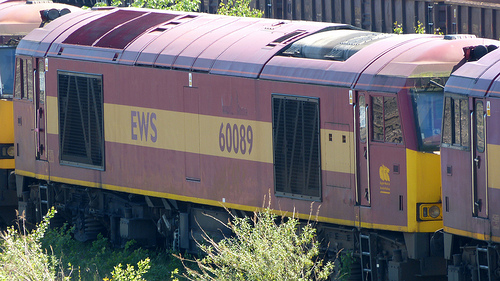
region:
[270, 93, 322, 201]
A metal ventilation grate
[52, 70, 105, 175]
A metal ventilation grate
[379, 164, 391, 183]
A yellow company logo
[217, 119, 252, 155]
An identification number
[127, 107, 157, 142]
The letters EWS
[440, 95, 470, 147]
A train windscreen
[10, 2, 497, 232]
A purple and yellow train car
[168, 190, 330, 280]
A green bush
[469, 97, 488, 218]
The door of a train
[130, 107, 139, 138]
The letter "E" in purple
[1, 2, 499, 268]
red and yellow abandoned train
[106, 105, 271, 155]
black letters and numbers on yellow stripe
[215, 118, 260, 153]
number 60089 on red train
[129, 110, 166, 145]
EWS on red train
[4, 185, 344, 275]
green bushes in foreground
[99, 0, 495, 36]
wooden fence in background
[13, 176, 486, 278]
black metal train wheels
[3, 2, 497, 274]
outdoor sunny daytime railroad scene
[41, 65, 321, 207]
black open doors on side of train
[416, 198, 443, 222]
round headlight in front of train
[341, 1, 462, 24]
brown train on track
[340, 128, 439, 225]
train has three colors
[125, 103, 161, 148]
ews is on the train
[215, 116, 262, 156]
60089 is on the train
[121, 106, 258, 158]
letters and numbers on tan area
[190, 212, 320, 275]
bush is green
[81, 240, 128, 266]
grass is green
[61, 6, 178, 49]
opening ontop of train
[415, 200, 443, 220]
light is round on train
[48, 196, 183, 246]
bottom of train is black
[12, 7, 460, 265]
red and yellow train engine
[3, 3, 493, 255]
three train engines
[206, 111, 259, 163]
numbers painted on engine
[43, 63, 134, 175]
exhaust vent on train engine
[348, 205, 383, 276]
steps to train entrance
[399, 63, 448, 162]
windshield on train engine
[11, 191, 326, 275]
overgrown weeds beside tracks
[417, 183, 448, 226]
headlight on train engine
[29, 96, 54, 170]
handrail on train entrance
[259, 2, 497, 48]
train cars behind engines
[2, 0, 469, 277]
a train sitting on the track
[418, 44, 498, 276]
part of a train behind the middle segment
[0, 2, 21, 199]
another segment in front of the other one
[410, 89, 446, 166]
a big window in the front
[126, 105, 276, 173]
some writing on the side of the train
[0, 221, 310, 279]
some bushes next to the train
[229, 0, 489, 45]
another train on another track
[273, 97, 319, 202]
a door on the train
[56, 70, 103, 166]
another door on the train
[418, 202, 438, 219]
a light on the train